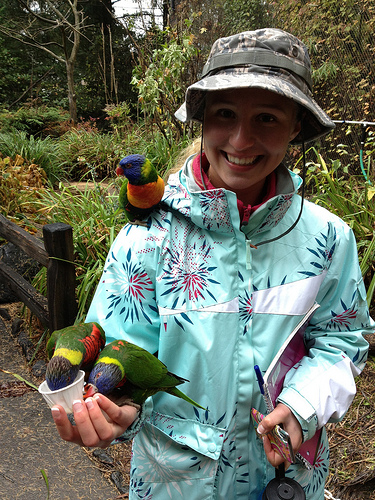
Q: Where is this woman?
A: A bird sanctuary.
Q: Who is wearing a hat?
A: The woman.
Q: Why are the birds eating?
A: She has food.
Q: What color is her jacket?
A: Pale blue.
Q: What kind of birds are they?
A: Tropical.